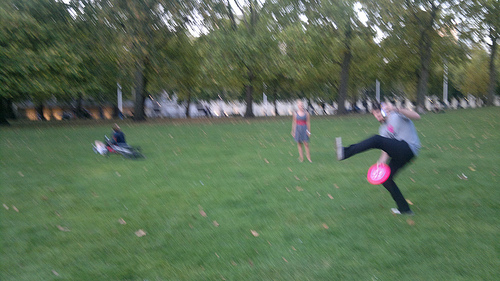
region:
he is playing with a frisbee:
[318, 74, 458, 223]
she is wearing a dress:
[275, 73, 339, 183]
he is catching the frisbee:
[328, 67, 448, 218]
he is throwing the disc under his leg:
[318, 60, 455, 251]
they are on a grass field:
[91, 69, 498, 269]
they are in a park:
[51, 53, 434, 278]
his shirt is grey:
[321, 57, 461, 244]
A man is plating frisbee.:
[337, 105, 431, 227]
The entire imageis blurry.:
[0, 0, 499, 280]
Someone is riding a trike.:
[94, 123, 147, 159]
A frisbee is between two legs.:
[339, 135, 408, 215]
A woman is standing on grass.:
[291, 98, 313, 165]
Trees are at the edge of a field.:
[0, 30, 495, 126]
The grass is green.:
[0, 106, 498, 278]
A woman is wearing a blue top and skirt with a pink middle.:
[289, 112, 314, 142]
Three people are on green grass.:
[96, 97, 422, 212]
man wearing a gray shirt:
[373, 105, 423, 151]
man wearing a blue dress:
[290, 106, 315, 151]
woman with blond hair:
[290, 95, 308, 111]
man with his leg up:
[326, 120, 409, 159]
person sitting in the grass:
[83, 112, 150, 172]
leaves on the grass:
[113, 208, 148, 243]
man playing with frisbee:
[302, 82, 423, 232]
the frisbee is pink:
[364, 148, 396, 202]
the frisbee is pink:
[354, 148, 388, 188]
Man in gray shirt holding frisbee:
[336, 95, 433, 214]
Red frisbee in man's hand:
[366, 155, 391, 184]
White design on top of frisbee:
[371, 165, 383, 179]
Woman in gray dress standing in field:
[289, 98, 312, 163]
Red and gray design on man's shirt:
[384, 123, 396, 136]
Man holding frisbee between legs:
[336, 96, 422, 213]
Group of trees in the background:
[1, 2, 498, 124]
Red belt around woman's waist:
[295, 118, 305, 124]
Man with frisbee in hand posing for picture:
[333, 100, 423, 217]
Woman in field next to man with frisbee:
[289, 98, 313, 163]